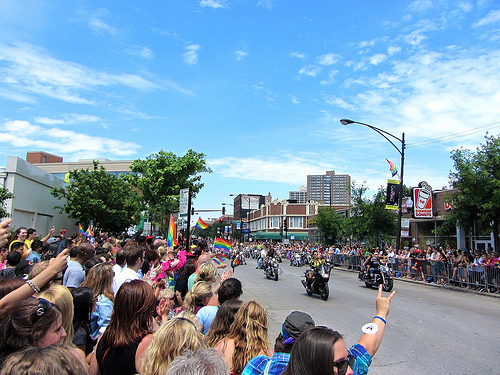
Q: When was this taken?
A: Daytime.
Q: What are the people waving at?
A: Motorcyclists.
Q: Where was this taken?
A: At a motorcycle rally.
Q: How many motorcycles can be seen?
A: Three.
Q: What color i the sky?
A: Blue.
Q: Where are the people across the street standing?
A: Behind a barricade.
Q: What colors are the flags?
A: Red, yellow, blue.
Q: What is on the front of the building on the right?
A: Sign of a cup of coffee.